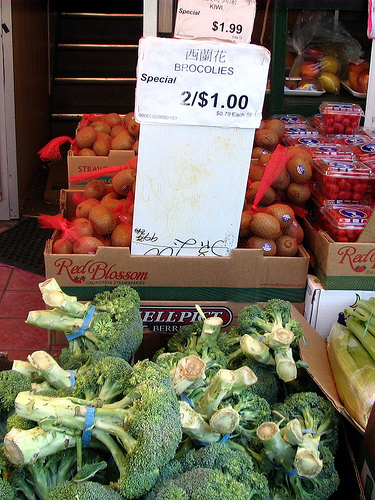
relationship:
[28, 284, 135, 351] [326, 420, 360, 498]
broccoli laying in box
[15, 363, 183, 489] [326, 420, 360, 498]
broccoli laying in box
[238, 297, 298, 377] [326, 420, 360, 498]
broccoli laying in box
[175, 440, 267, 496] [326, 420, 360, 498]
broccoli laying in box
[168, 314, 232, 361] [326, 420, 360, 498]
broccoli laying in box